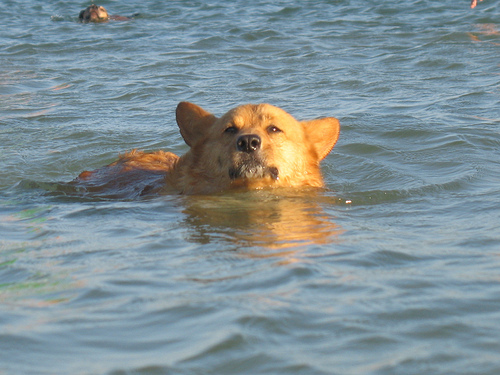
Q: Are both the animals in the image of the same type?
A: Yes, all the animals are dogs.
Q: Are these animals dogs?
A: Yes, all the animals are dogs.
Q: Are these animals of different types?
A: No, all the animals are dogs.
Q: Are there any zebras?
A: No, there are no zebras.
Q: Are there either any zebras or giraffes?
A: No, there are no zebras or giraffes.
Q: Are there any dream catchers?
A: No, there are no dream catchers.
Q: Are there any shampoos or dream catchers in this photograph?
A: No, there are no dream catchers or shampoos.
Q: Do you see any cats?
A: No, there are no cats.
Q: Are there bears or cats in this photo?
A: No, there are no cats or bears.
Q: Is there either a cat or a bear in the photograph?
A: No, there are no cats or bears.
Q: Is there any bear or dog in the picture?
A: Yes, there is a dog.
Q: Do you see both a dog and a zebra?
A: No, there is a dog but no zebras.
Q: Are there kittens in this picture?
A: No, there are no kittens.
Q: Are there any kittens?
A: No, there are no kittens.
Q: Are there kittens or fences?
A: No, there are no kittens or fences.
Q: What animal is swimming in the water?
A: The dog is swimming in the water.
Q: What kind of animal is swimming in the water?
A: The animal is a dog.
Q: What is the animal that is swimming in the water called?
A: The animal is a dog.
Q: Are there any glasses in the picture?
A: No, there are no glasses.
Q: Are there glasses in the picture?
A: No, there are no glasses.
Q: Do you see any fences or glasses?
A: No, there are no glasses or fences.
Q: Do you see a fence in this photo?
A: No, there are no fences.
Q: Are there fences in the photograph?
A: No, there are no fences.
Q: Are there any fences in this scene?
A: No, there are no fences.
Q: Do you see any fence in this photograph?
A: No, there are no fences.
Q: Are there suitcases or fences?
A: No, there are no fences or suitcases.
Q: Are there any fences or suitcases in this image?
A: No, there are no fences or suitcases.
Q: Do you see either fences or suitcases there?
A: No, there are no fences or suitcases.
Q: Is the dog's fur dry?
A: No, the fur is wet.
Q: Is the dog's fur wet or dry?
A: The fur is wet.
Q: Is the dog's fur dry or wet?
A: The fur is wet.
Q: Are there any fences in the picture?
A: No, there are no fences.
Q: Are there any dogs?
A: Yes, there is a dog.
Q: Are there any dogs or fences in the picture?
A: Yes, there is a dog.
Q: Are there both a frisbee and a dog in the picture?
A: No, there is a dog but no frisbees.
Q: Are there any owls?
A: No, there are no owls.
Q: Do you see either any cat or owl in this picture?
A: No, there are no owls or cats.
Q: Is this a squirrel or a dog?
A: This is a dog.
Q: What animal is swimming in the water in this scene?
A: The dog is swimming in the water.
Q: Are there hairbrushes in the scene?
A: No, there are no hairbrushes.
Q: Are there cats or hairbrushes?
A: No, there are no hairbrushes or cats.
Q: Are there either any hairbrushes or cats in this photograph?
A: No, there are no hairbrushes or cats.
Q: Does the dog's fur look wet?
A: Yes, the fur is wet.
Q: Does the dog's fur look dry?
A: No, the fur is wet.